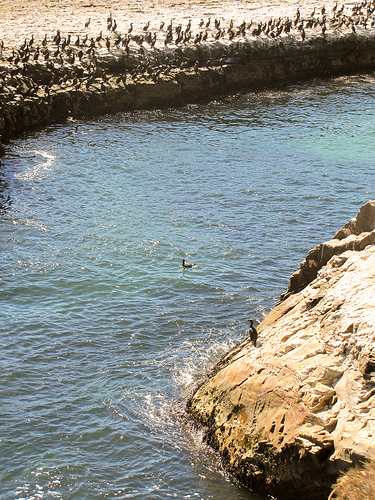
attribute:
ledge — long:
[1, 14, 347, 132]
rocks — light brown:
[183, 210, 372, 490]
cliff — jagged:
[175, 17, 349, 82]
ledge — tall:
[174, 189, 363, 497]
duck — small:
[168, 250, 211, 277]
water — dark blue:
[27, 141, 317, 296]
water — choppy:
[192, 126, 343, 202]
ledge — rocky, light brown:
[164, 198, 372, 499]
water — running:
[1, 72, 373, 498]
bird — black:
[246, 316, 260, 349]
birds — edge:
[168, 235, 224, 308]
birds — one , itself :
[249, 306, 266, 347]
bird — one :
[243, 308, 260, 343]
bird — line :
[244, 317, 265, 349]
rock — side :
[217, 357, 320, 414]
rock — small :
[230, 346, 305, 369]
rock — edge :
[240, 344, 349, 398]